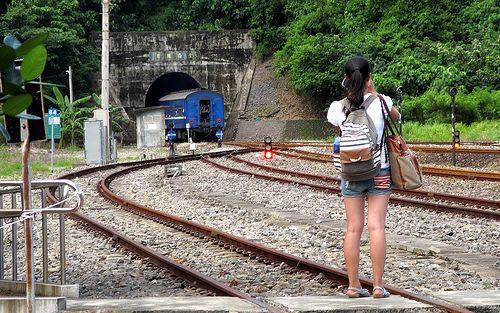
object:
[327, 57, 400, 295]
girl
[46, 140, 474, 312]
track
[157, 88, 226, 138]
train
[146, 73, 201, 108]
tunnel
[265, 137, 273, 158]
light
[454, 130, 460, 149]
light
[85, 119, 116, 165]
box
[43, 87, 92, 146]
tree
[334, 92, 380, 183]
backpack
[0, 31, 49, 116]
leaves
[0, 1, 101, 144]
tree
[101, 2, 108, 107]
pole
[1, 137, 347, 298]
rocks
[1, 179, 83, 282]
rail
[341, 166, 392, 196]
shorts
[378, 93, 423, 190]
bag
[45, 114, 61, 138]
sign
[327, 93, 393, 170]
shirt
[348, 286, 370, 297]
sandal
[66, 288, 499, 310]
walkway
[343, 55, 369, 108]
ponytail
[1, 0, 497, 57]
trees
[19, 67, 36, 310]
tree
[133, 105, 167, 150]
shack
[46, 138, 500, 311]
tracks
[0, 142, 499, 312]
ground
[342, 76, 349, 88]
phone